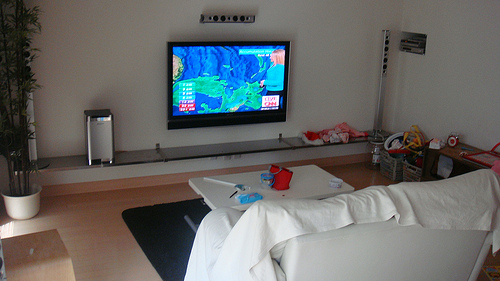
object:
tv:
[167, 40, 292, 129]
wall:
[0, 0, 499, 188]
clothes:
[298, 122, 369, 145]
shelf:
[19, 131, 389, 175]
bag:
[268, 163, 293, 191]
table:
[188, 165, 357, 213]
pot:
[1, 184, 45, 220]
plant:
[0, 0, 44, 198]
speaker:
[200, 12, 256, 24]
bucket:
[371, 143, 381, 166]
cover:
[182, 169, 500, 280]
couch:
[182, 168, 497, 280]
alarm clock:
[447, 132, 460, 147]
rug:
[118, 198, 211, 281]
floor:
[1, 157, 497, 281]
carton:
[380, 150, 404, 182]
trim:
[32, 153, 376, 198]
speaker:
[373, 29, 393, 138]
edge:
[165, 118, 287, 130]